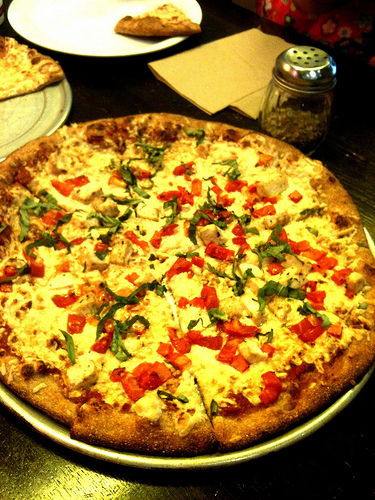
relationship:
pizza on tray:
[1, 109, 373, 457] [1, 222, 372, 476]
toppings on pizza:
[7, 146, 357, 406] [1, 109, 373, 457]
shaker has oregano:
[258, 45, 337, 158] [257, 106, 327, 157]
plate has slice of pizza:
[4, 2, 204, 58] [112, 4, 204, 40]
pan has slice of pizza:
[0, 79, 74, 165] [1, 35, 65, 103]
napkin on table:
[146, 27, 297, 120] [3, 1, 374, 496]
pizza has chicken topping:
[1, 109, 373, 457] [11, 154, 362, 419]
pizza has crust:
[1, 109, 373, 457] [2, 111, 374, 457]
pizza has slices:
[1, 109, 373, 457] [2, 113, 372, 458]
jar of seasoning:
[258, 45, 337, 158] [257, 106, 327, 157]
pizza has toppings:
[1, 109, 373, 457] [7, 146, 357, 406]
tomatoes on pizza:
[0, 166, 355, 407] [1, 109, 373, 457]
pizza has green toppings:
[1, 109, 373, 457] [3, 128, 366, 414]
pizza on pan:
[1, 109, 373, 457] [1, 222, 372, 476]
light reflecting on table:
[2, 414, 219, 500] [3, 1, 374, 496]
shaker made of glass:
[258, 45, 337, 158] [260, 80, 333, 160]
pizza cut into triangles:
[1, 109, 373, 457] [2, 113, 372, 458]